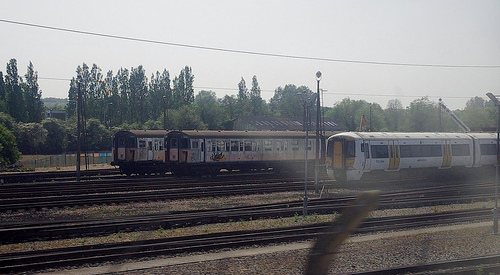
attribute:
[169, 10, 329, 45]
sky — white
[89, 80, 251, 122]
trees — green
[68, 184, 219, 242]
tracks — brown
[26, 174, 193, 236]
tracks — parallel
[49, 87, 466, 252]
picture — daytime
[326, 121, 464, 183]
train — white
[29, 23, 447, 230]
scene — outdoors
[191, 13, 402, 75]
sky — overcast, grey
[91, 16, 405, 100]
cables — hanging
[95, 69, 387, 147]
leaves — green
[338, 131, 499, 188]
train — white, yellow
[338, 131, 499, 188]
door — yellow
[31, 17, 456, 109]
wire — electric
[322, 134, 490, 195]
car — white, yellow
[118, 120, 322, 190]
cars — silver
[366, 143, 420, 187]
door — yellow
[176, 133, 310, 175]
graffiti — black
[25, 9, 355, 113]
sky — gray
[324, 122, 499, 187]
train — white, long, yellow, black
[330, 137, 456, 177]
doors — yellow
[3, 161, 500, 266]
tracks — rail, long, metal, set, a set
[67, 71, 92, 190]
pole — grey, tall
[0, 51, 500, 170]
trees — tall, green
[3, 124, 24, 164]
bush — green, thick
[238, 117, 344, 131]
roof — brown